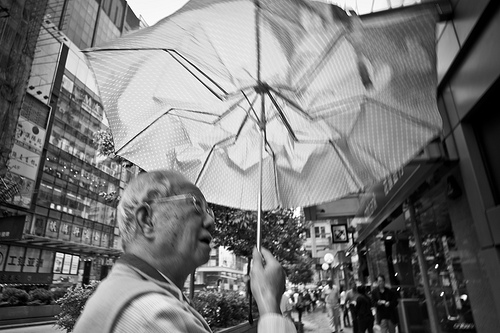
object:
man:
[68, 169, 300, 332]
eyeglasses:
[143, 192, 215, 218]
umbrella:
[76, 0, 447, 251]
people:
[353, 275, 401, 333]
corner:
[323, 287, 370, 325]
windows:
[31, 144, 121, 252]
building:
[0, 0, 148, 284]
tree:
[206, 199, 305, 274]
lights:
[321, 253, 336, 271]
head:
[117, 169, 218, 268]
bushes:
[184, 287, 261, 331]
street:
[248, 318, 314, 332]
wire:
[223, 91, 261, 164]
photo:
[0, 0, 500, 333]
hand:
[249, 245, 289, 308]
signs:
[330, 222, 358, 244]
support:
[221, 85, 309, 249]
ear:
[134, 203, 155, 241]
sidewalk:
[299, 293, 378, 333]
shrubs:
[183, 285, 259, 331]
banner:
[2, 116, 48, 208]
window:
[406, 205, 452, 279]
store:
[345, 131, 484, 333]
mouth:
[198, 235, 212, 249]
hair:
[116, 167, 188, 252]